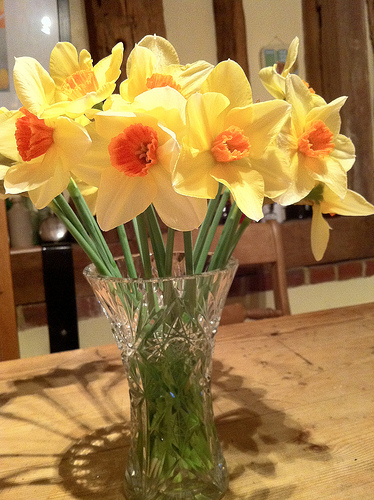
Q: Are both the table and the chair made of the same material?
A: Yes, both the table and the chair are made of wood.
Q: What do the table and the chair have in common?
A: The material, both the table and the chair are wooden.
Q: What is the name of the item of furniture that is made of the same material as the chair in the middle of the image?
A: The piece of furniture is a table.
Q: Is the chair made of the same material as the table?
A: Yes, both the chair and the table are made of wood.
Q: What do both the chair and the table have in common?
A: The material, both the chair and the table are wooden.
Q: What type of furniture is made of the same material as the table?
A: The chair is made of the same material as the table.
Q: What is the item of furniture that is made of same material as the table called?
A: The piece of furniture is a chair.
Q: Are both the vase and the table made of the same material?
A: No, the vase is made of glass and the table is made of wood.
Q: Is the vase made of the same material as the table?
A: No, the vase is made of glass and the table is made of wood.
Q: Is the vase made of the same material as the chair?
A: No, the vase is made of glass and the chair is made of wood.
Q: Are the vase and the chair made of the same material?
A: No, the vase is made of glass and the chair is made of wood.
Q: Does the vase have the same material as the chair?
A: No, the vase is made of glass and the chair is made of wood.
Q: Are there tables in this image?
A: Yes, there is a table.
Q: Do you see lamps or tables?
A: Yes, there is a table.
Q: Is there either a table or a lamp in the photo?
A: Yes, there is a table.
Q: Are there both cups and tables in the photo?
A: No, there is a table but no cups.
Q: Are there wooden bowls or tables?
A: Yes, there is a wood table.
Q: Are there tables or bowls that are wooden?
A: Yes, the table is wooden.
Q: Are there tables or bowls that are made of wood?
A: Yes, the table is made of wood.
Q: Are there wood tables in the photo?
A: Yes, there is a wood table.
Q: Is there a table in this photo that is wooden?
A: Yes, there is a table that is wooden.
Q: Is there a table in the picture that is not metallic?
A: Yes, there is a wooden table.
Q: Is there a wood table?
A: Yes, there is a table that is made of wood.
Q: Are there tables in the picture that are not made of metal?
A: Yes, there is a table that is made of wood.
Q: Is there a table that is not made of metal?
A: Yes, there is a table that is made of wood.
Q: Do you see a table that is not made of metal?
A: Yes, there is a table that is made of wood.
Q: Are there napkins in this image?
A: No, there are no napkins.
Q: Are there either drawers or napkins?
A: No, there are no napkins or drawers.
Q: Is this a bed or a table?
A: This is a table.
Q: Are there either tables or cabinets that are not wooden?
A: No, there is a table but it is wooden.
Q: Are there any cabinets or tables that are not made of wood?
A: No, there is a table but it is made of wood.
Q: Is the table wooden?
A: Yes, the table is wooden.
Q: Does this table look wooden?
A: Yes, the table is wooden.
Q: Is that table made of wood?
A: Yes, the table is made of wood.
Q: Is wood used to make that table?
A: Yes, the table is made of wood.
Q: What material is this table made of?
A: The table is made of wood.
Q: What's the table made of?
A: The table is made of wood.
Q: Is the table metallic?
A: No, the table is wooden.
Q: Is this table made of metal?
A: No, the table is made of wood.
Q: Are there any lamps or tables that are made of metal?
A: No, there is a table but it is made of wood.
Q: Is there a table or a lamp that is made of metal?
A: No, there is a table but it is made of wood.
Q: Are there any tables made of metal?
A: No, there is a table but it is made of wood.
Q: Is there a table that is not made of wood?
A: No, there is a table but it is made of wood.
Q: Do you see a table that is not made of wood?
A: No, there is a table but it is made of wood.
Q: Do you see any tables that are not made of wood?
A: No, there is a table but it is made of wood.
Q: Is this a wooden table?
A: Yes, this is a wooden table.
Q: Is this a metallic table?
A: No, this is a wooden table.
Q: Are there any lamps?
A: No, there are no lamps.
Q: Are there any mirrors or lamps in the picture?
A: No, there are no lamps or mirrors.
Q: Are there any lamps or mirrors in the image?
A: No, there are no lamps or mirrors.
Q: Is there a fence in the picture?
A: No, there are no fences.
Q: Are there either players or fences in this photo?
A: No, there are no fences or players.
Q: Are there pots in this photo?
A: No, there are no pots.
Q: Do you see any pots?
A: No, there are no pots.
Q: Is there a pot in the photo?
A: No, there are no pots.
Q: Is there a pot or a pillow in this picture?
A: No, there are no pots or pillows.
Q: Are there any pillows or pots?
A: No, there are no pots or pillows.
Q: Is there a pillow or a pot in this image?
A: No, there are no pots or pillows.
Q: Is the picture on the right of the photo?
A: Yes, the picture is on the right of the image.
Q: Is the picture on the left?
A: No, the picture is on the right of the image.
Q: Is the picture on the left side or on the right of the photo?
A: The picture is on the right of the image.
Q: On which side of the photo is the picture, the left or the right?
A: The picture is on the right of the image.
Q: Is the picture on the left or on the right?
A: The picture is on the right of the image.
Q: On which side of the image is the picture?
A: The picture is on the right of the image.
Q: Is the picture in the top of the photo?
A: Yes, the picture is in the top of the image.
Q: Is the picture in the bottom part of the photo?
A: No, the picture is in the top of the image.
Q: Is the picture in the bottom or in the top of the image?
A: The picture is in the top of the image.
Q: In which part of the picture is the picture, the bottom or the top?
A: The picture is in the top of the image.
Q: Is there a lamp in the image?
A: No, there are no lamps.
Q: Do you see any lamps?
A: No, there are no lamps.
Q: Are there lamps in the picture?
A: No, there are no lamps.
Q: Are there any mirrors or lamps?
A: No, there are no lamps or mirrors.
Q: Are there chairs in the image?
A: Yes, there is a chair.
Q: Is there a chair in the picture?
A: Yes, there is a chair.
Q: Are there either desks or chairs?
A: Yes, there is a chair.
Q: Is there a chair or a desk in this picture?
A: Yes, there is a chair.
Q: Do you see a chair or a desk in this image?
A: Yes, there is a chair.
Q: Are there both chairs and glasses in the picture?
A: No, there is a chair but no glasses.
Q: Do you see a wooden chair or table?
A: Yes, there is a wood chair.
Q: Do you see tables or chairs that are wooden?
A: Yes, the chair is wooden.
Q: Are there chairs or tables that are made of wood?
A: Yes, the chair is made of wood.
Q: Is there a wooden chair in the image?
A: Yes, there is a wood chair.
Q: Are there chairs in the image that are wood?
A: Yes, there is a wood chair.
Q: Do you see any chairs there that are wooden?
A: Yes, there is a chair that is wooden.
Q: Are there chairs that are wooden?
A: Yes, there is a chair that is wooden.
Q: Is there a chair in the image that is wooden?
A: Yes, there is a chair that is wooden.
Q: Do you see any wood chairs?
A: Yes, there is a chair that is made of wood.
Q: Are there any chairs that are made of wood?
A: Yes, there is a chair that is made of wood.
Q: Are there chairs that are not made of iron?
A: Yes, there is a chair that is made of wood.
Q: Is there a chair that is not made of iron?
A: Yes, there is a chair that is made of wood.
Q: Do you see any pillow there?
A: No, there are no pillows.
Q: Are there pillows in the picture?
A: No, there are no pillows.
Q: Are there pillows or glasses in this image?
A: No, there are no pillows or glasses.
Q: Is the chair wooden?
A: Yes, the chair is wooden.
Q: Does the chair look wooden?
A: Yes, the chair is wooden.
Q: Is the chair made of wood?
A: Yes, the chair is made of wood.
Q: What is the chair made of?
A: The chair is made of wood.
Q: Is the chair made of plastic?
A: No, the chair is made of wood.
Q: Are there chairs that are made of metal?
A: No, there is a chair but it is made of wood.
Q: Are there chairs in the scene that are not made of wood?
A: No, there is a chair but it is made of wood.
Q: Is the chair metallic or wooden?
A: The chair is wooden.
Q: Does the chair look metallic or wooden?
A: The chair is wooden.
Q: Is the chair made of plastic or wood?
A: The chair is made of wood.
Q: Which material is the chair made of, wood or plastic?
A: The chair is made of wood.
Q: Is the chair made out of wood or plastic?
A: The chair is made of wood.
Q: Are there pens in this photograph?
A: No, there are no pens.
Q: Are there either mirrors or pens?
A: No, there are no pens or mirrors.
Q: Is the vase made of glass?
A: Yes, the vase is made of glass.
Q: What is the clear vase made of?
A: The vase is made of glass.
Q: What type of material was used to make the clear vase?
A: The vase is made of glass.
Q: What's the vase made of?
A: The vase is made of glass.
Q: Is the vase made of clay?
A: No, the vase is made of glass.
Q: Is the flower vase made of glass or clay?
A: The vase is made of glass.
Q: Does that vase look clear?
A: Yes, the vase is clear.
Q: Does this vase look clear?
A: Yes, the vase is clear.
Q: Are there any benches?
A: No, there are no benches.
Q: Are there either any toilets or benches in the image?
A: No, there are no benches or toilets.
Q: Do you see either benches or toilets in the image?
A: No, there are no benches or toilets.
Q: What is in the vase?
A: The flower is in the vase.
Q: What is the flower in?
A: The flower is in the vase.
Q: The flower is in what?
A: The flower is in the vase.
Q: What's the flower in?
A: The flower is in the vase.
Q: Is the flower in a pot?
A: No, the flower is in the vase.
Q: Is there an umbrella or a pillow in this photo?
A: No, there are no pillows or umbrellas.